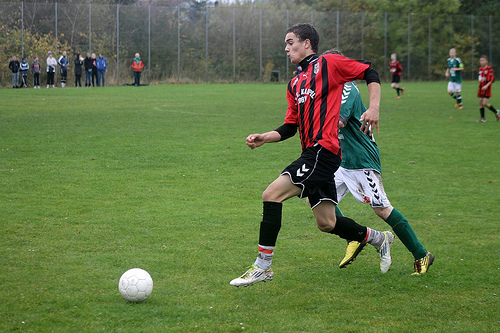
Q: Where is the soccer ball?
A: In the grass.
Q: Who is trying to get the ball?
A: The soccer players.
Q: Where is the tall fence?
A: Behind all of the people.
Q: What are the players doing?
A: Running for ball.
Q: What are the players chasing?
A: Ball.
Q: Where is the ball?
A: Ground.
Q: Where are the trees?
A: Outside fence.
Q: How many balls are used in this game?
A: One.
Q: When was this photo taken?
A: Daytime.